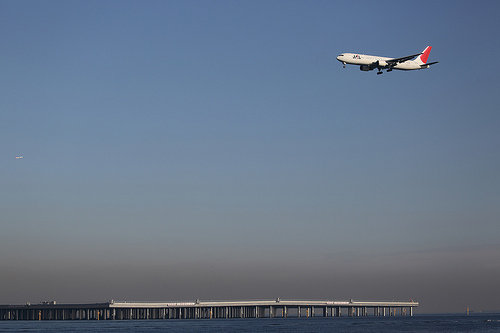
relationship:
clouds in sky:
[0, 0, 500, 312] [99, 45, 256, 162]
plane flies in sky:
[317, 28, 451, 88] [217, 72, 334, 162]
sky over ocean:
[4, 9, 327, 99] [32, 318, 212, 331]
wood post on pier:
[222, 305, 230, 320] [141, 289, 423, 313]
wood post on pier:
[236, 306, 251, 321] [141, 289, 423, 313]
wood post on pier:
[263, 302, 280, 320] [141, 289, 423, 313]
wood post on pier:
[294, 302, 302, 321] [141, 289, 423, 313]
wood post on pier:
[189, 307, 200, 318] [141, 289, 423, 313]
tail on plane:
[415, 43, 435, 64] [335, 44, 441, 77]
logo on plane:
[351, 50, 363, 60] [335, 44, 441, 77]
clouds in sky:
[0, 0, 500, 312] [2, 0, 500, 313]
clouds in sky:
[64, 205, 487, 277] [3, 4, 494, 313]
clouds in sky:
[0, 0, 500, 312] [50, 128, 209, 205]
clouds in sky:
[0, 0, 500, 312] [15, 7, 488, 295]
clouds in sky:
[0, 0, 500, 312] [3, 4, 494, 313]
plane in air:
[335, 44, 441, 77] [62, 20, 472, 157]